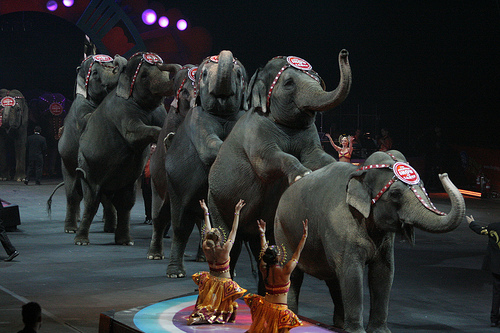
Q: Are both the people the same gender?
A: No, they are both male and female.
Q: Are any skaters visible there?
A: No, there are no skaters.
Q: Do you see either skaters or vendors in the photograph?
A: No, there are no skaters or vendors.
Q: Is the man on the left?
A: Yes, the man is on the left of the image.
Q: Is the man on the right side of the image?
A: No, the man is on the left of the image.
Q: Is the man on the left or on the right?
A: The man is on the left of the image.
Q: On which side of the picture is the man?
A: The man is on the left of the image.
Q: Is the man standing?
A: Yes, the man is standing.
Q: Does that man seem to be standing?
A: Yes, the man is standing.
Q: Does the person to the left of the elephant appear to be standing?
A: Yes, the man is standing.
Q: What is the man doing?
A: The man is standing.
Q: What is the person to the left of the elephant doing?
A: The man is standing.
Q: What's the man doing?
A: The man is standing.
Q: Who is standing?
A: The man is standing.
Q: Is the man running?
A: No, the man is standing.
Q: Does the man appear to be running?
A: No, the man is standing.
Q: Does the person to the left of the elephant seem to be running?
A: No, the man is standing.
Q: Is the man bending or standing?
A: The man is standing.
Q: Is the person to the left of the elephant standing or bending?
A: The man is standing.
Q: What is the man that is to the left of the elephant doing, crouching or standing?
A: The man is standing.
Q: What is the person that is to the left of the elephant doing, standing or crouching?
A: The man is standing.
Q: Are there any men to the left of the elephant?
A: Yes, there is a man to the left of the elephant.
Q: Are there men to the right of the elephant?
A: No, the man is to the left of the elephant.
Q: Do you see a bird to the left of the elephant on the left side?
A: No, there is a man to the left of the elephant.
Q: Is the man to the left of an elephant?
A: Yes, the man is to the left of an elephant.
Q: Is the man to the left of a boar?
A: No, the man is to the left of an elephant.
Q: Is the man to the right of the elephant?
A: No, the man is to the left of the elephant.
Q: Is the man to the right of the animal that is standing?
A: No, the man is to the left of the elephant.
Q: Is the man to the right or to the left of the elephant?
A: The man is to the left of the elephant.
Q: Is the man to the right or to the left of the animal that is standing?
A: The man is to the left of the elephant.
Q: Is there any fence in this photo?
A: No, there are no fences.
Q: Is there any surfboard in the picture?
A: No, there are no surfboards.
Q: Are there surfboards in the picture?
A: No, there are no surfboards.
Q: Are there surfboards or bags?
A: No, there are no surfboards or bags.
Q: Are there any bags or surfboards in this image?
A: No, there are no surfboards or bags.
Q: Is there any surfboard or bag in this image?
A: No, there are no surfboards or bags.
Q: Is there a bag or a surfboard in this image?
A: No, there are no surfboards or bags.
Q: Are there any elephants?
A: Yes, there is an elephant.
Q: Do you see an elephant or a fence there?
A: Yes, there is an elephant.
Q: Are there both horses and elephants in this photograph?
A: No, there is an elephant but no horses.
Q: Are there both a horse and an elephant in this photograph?
A: No, there is an elephant but no horses.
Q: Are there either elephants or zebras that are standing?
A: Yes, the elephant is standing.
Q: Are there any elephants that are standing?
A: Yes, there is an elephant that is standing.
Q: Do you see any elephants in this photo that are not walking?
A: Yes, there is an elephant that is standing .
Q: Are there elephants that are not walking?
A: Yes, there is an elephant that is standing.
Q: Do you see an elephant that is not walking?
A: Yes, there is an elephant that is standing .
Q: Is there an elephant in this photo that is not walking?
A: Yes, there is an elephant that is standing.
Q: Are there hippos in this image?
A: No, there are no hippos.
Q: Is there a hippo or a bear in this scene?
A: No, there are no hippos or bears.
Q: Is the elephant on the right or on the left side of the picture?
A: The elephant is on the left of the image.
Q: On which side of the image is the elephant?
A: The elephant is on the left of the image.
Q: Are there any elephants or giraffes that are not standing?
A: No, there is an elephant but it is standing.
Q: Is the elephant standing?
A: Yes, the elephant is standing.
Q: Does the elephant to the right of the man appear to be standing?
A: Yes, the elephant is standing.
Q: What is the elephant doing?
A: The elephant is standing.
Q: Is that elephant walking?
A: No, the elephant is standing.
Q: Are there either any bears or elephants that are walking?
A: No, there is an elephant but it is standing.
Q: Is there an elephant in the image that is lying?
A: No, there is an elephant but it is standing.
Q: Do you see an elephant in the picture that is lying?
A: No, there is an elephant but it is standing.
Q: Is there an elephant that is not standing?
A: No, there is an elephant but it is standing.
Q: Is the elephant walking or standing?
A: The elephant is standing.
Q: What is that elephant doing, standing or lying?
A: The elephant is standing.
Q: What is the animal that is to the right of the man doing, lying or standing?
A: The elephant is standing.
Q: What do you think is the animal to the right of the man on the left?
A: The animal is an elephant.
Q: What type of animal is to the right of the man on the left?
A: The animal is an elephant.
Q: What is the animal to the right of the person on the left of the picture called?
A: The animal is an elephant.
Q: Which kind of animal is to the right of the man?
A: The animal is an elephant.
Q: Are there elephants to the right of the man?
A: Yes, there is an elephant to the right of the man.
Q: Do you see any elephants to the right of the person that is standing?
A: Yes, there is an elephant to the right of the man.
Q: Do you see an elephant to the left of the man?
A: No, the elephant is to the right of the man.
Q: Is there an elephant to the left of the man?
A: No, the elephant is to the right of the man.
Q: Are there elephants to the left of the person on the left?
A: No, the elephant is to the right of the man.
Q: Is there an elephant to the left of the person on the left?
A: No, the elephant is to the right of the man.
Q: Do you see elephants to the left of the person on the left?
A: No, the elephant is to the right of the man.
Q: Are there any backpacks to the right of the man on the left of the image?
A: No, there is an elephant to the right of the man.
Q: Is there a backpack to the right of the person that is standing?
A: No, there is an elephant to the right of the man.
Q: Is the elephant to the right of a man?
A: Yes, the elephant is to the right of a man.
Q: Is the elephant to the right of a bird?
A: No, the elephant is to the right of a man.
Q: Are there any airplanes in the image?
A: No, there are no airplanes.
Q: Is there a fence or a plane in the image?
A: No, there are no airplanes or fences.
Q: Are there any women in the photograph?
A: Yes, there is a woman.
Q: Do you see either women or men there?
A: Yes, there is a woman.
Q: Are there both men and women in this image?
A: Yes, there are both a woman and a man.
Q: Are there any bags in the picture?
A: No, there are no bags.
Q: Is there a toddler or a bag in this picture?
A: No, there are no bags or toddlers.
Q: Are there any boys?
A: No, there are no boys.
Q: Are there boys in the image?
A: No, there are no boys.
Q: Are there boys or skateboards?
A: No, there are no boys or skateboards.